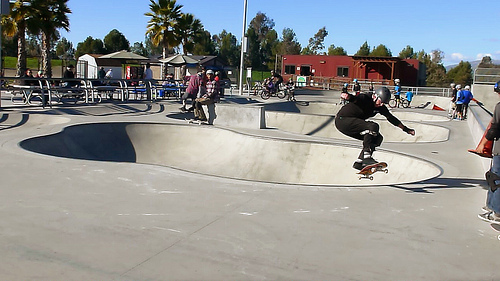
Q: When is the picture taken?
A: Day time.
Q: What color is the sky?
A: Blue.